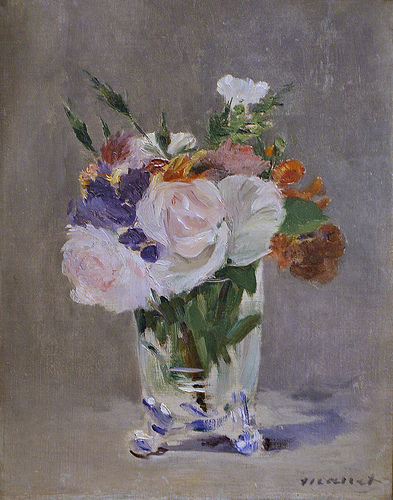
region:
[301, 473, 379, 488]
a painter's name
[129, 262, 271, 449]
a drawn glass vase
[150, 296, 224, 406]
the stem of a plant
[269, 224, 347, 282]
the head of a red flower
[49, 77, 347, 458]
a vase full of flowers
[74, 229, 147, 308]
a white and pink flower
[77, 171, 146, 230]
a collection of purple flowers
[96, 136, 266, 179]
a cluster of assorted flowers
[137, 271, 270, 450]
a glass vase holding flowers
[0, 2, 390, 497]
a painting of a vase of flowers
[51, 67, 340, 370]
a painted bouquet of flowers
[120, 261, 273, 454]
a footed vase of clear glass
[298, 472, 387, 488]
name of the artist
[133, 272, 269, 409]
stems and leaves of flowers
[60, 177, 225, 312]
pink roses make focal point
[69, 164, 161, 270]
a section of purple flowers by the pink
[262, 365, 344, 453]
a shadow of the vased flowers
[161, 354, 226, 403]
the light reflected off the glass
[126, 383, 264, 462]
the blue repersents thicker glass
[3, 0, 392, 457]
a taupe colored background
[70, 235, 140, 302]
a flower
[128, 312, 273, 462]
a clear vase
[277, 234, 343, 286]
a brown flower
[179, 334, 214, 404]
a brown stem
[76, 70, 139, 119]
green leaves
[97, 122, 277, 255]
flowers in the vase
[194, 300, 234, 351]
green leaves in the vase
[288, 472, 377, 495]
writing on the picture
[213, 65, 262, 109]
a white flower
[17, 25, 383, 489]
picture of a painting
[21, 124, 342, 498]
flowers in a vase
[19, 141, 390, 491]
a painting of flowers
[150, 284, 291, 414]
leaves in the vase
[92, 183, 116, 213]
purple flowers in a vase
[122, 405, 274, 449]
the vase has blue highlights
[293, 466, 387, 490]
the name of the painter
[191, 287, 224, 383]
the vase has green leaves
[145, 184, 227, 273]
the vase has a rose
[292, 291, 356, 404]
the background is light gray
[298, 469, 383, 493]
Signature of artist in dark lettering.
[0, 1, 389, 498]
Painting offlowers on gray background.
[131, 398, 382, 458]
Shadow painted near feet and on right.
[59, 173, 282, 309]
Painting of white and blue flowers,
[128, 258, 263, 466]
Vase with multiple colors on it.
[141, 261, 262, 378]
Mostly spruce green lines vertical or diagonal.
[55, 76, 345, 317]
Orange, blue white and a red flower image.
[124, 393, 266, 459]
Two vase feet with mostly blue and white coloring.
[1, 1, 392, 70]
Gray area with light spots and lines.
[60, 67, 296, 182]
Flower painting with green leaves.